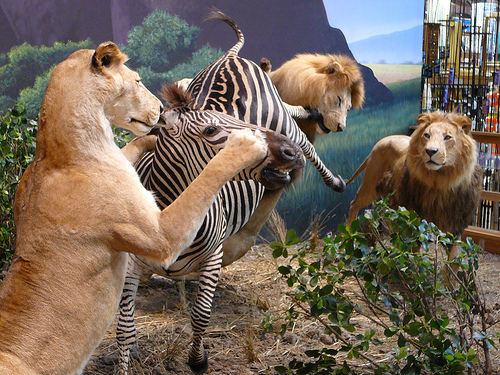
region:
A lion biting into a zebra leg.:
[258, 52, 365, 140]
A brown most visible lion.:
[342, 107, 479, 242]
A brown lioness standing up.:
[1, 41, 267, 373]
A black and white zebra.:
[116, 6, 347, 373]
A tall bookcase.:
[420, 1, 499, 251]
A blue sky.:
[322, 2, 426, 64]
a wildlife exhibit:
[36, 22, 486, 358]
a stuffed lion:
[341, 85, 488, 322]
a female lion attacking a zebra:
[1, 34, 376, 364]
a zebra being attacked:
[70, 12, 412, 360]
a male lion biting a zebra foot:
[216, 21, 413, 231]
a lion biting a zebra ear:
[27, 18, 351, 264]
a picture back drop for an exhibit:
[8, 1, 465, 311]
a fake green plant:
[264, 181, 488, 373]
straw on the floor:
[136, 199, 476, 374]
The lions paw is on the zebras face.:
[10, 35, 245, 373]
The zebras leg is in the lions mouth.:
[265, 65, 355, 140]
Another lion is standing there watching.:
[352, 110, 476, 240]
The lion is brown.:
[357, 105, 478, 242]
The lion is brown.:
[0, 36, 261, 369]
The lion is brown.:
[266, 55, 368, 147]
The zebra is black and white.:
[118, 80, 301, 373]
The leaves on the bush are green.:
[266, 215, 499, 373]